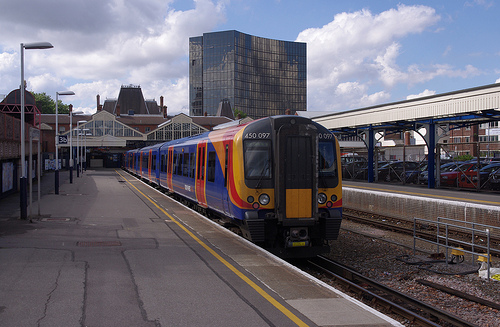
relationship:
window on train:
[206, 150, 217, 182] [118, 113, 346, 260]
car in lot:
[375, 162, 420, 179] [348, 154, 498, 191]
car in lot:
[439, 162, 481, 185] [339, 153, 499, 193]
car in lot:
[373, 158, 426, 184] [339, 153, 499, 193]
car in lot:
[344, 160, 372, 177] [339, 153, 499, 193]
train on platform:
[118, 113, 346, 260] [0, 167, 405, 325]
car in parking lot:
[440, 160, 481, 182] [344, 144, 499, 192]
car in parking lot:
[373, 158, 426, 184] [336, 142, 498, 189]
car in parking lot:
[373, 158, 426, 184] [343, 150, 498, 199]